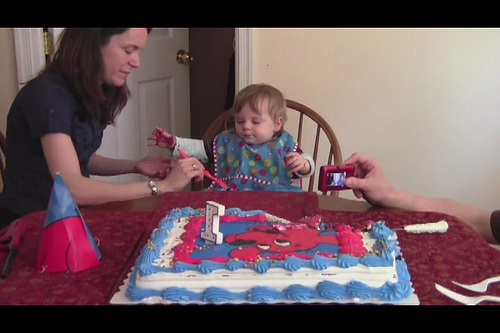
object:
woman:
[0, 25, 207, 228]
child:
[169, 83, 317, 197]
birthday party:
[26, 169, 486, 308]